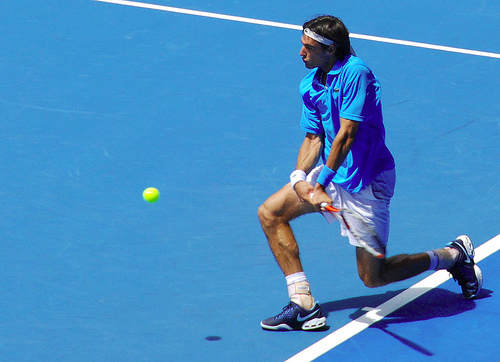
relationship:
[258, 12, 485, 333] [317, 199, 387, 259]
man holding racket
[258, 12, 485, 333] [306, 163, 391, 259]
man wearing shorts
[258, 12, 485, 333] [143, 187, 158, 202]
man hitting ball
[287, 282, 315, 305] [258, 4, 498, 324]
brace on man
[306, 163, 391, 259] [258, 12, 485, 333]
shorts are on man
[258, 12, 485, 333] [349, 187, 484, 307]
man has leg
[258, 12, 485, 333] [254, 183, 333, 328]
man has leg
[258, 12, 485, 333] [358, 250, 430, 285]
man has leg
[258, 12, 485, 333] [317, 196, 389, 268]
man swinging racket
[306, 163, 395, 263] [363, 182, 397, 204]
shorts has pocket